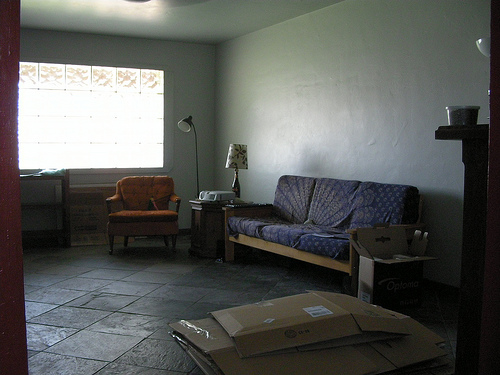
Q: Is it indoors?
A: Yes, it is indoors.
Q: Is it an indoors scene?
A: Yes, it is indoors.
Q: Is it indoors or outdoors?
A: It is indoors.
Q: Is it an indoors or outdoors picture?
A: It is indoors.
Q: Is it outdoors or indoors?
A: It is indoors.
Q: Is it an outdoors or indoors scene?
A: It is indoors.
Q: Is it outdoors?
A: No, it is indoors.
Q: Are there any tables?
A: Yes, there is a table.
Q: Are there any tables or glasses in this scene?
A: Yes, there is a table.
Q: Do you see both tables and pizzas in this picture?
A: No, there is a table but no pizzas.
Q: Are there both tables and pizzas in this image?
A: No, there is a table but no pizzas.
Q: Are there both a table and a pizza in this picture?
A: No, there is a table but no pizzas.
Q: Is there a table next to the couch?
A: Yes, there is a table next to the couch.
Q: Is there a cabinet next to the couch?
A: No, there is a table next to the couch.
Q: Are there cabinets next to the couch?
A: No, there is a table next to the couch.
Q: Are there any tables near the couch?
A: Yes, there is a table near the couch.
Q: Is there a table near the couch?
A: Yes, there is a table near the couch.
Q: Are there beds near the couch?
A: No, there is a table near the couch.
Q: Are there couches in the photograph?
A: Yes, there is a couch.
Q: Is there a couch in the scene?
A: Yes, there is a couch.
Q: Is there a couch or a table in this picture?
A: Yes, there is a couch.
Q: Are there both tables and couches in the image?
A: Yes, there are both a couch and a table.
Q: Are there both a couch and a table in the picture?
A: Yes, there are both a couch and a table.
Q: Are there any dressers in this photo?
A: No, there are no dressers.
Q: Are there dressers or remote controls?
A: No, there are no dressers or remote controls.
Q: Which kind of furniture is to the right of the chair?
A: The piece of furniture is a couch.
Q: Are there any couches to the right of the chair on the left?
A: Yes, there is a couch to the right of the chair.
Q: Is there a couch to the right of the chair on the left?
A: Yes, there is a couch to the right of the chair.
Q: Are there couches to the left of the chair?
A: No, the couch is to the right of the chair.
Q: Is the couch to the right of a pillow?
A: No, the couch is to the right of the chair.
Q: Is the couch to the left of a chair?
A: No, the couch is to the right of a chair.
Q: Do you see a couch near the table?
A: Yes, there is a couch near the table.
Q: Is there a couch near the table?
A: Yes, there is a couch near the table.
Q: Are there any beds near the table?
A: No, there is a couch near the table.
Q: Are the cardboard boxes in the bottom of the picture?
A: Yes, the boxes are in the bottom of the image.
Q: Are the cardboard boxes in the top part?
A: No, the boxes are in the bottom of the image.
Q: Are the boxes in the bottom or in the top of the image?
A: The boxes are in the bottom of the image.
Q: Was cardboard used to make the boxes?
A: Yes, the boxes are made of cardboard.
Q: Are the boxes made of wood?
A: No, the boxes are made of cardboard.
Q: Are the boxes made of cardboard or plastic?
A: The boxes are made of cardboard.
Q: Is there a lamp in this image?
A: Yes, there is a lamp.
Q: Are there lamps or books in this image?
A: Yes, there is a lamp.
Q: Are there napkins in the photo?
A: No, there are no napkins.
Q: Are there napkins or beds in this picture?
A: No, there are no napkins or beds.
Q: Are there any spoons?
A: No, there are no spoons.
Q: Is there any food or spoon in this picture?
A: No, there are no spoons or food.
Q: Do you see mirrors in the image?
A: No, there are no mirrors.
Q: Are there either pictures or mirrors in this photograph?
A: No, there are no mirrors or pictures.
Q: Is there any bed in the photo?
A: No, there are no beds.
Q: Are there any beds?
A: No, there are no beds.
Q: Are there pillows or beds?
A: No, there are no beds or pillows.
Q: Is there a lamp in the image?
A: Yes, there is a lamp.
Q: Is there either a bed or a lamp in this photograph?
A: Yes, there is a lamp.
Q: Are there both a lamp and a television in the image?
A: No, there is a lamp but no televisions.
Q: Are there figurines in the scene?
A: No, there are no figurines.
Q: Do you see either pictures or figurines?
A: No, there are no figurines or pictures.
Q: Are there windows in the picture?
A: Yes, there is a window.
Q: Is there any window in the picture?
A: Yes, there is a window.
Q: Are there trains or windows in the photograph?
A: Yes, there is a window.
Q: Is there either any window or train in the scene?
A: Yes, there is a window.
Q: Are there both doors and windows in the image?
A: No, there is a window but no doors.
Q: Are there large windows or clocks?
A: Yes, there is a large window.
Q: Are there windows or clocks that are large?
A: Yes, the window is large.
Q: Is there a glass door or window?
A: Yes, there is a glass window.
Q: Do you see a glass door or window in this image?
A: Yes, there is a glass window.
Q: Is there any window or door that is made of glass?
A: Yes, the window is made of glass.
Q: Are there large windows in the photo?
A: Yes, there is a large window.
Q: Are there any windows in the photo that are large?
A: Yes, there is a window that is large.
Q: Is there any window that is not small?
A: Yes, there is a large window.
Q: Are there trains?
A: No, there are no trains.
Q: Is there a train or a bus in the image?
A: No, there are no trains or buses.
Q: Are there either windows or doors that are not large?
A: No, there is a window but it is large.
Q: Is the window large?
A: Yes, the window is large.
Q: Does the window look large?
A: Yes, the window is large.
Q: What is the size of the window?
A: The window is large.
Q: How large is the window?
A: The window is large.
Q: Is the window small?
A: No, the window is large.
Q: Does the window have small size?
A: No, the window is large.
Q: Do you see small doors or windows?
A: No, there is a window but it is large.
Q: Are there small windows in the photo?
A: No, there is a window but it is large.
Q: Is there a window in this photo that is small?
A: No, there is a window but it is large.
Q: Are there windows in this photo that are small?
A: No, there is a window but it is large.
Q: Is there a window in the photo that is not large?
A: No, there is a window but it is large.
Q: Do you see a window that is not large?
A: No, there is a window but it is large.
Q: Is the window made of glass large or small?
A: The window is large.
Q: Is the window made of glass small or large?
A: The window is large.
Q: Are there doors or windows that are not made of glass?
A: No, there is a window but it is made of glass.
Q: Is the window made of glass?
A: Yes, the window is made of glass.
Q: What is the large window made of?
A: The window is made of glass.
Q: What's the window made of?
A: The window is made of glass.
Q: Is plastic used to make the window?
A: No, the window is made of glass.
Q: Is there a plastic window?
A: No, there is a window but it is made of glass.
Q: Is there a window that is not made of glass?
A: No, there is a window but it is made of glass.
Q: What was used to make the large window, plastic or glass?
A: The window is made of glass.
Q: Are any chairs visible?
A: Yes, there is a chair.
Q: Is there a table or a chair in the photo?
A: Yes, there is a chair.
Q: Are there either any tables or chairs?
A: Yes, there is a chair.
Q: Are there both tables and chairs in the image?
A: Yes, there are both a chair and a table.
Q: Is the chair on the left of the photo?
A: Yes, the chair is on the left of the image.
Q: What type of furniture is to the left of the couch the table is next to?
A: The piece of furniture is a chair.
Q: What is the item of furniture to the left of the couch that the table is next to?
A: The piece of furniture is a chair.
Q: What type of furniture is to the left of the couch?
A: The piece of furniture is a chair.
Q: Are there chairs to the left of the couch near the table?
A: Yes, there is a chair to the left of the couch.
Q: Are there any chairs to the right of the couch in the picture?
A: No, the chair is to the left of the couch.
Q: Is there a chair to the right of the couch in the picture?
A: No, the chair is to the left of the couch.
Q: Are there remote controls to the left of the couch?
A: No, there is a chair to the left of the couch.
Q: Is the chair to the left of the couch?
A: Yes, the chair is to the left of the couch.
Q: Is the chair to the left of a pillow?
A: No, the chair is to the left of the couch.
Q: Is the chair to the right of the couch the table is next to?
A: No, the chair is to the left of the couch.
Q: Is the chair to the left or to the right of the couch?
A: The chair is to the left of the couch.